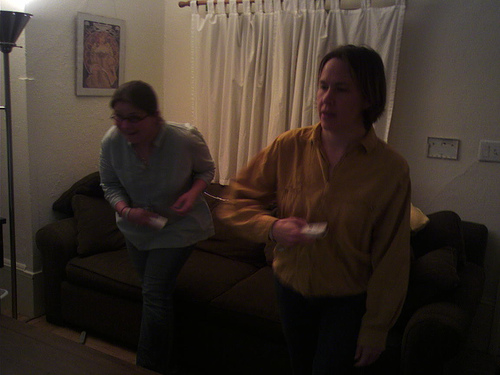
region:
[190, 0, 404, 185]
the white hanging curtain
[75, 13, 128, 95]
the picture is hanging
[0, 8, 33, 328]
the tall floor lamp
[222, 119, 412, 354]
the long sleeved mustard color shirt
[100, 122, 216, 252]
the long sleeved blue shirt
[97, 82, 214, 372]
the glasses on the person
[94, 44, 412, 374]
two people playing video games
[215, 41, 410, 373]
woman holding a Wii controller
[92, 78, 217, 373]
smiling woman wearing glasses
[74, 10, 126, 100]
artwork with white matting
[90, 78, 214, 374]
woman wearing a gray shirt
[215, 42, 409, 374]
woman wearing a tan shirt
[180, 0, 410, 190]
long white curtains hanging off wood rod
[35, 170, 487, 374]
brown cushion couch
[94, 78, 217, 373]
woman wearing blue jeans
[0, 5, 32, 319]
black metal floor lamp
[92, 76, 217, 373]
A person holding a game controller.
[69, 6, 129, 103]
A framed picture on a wall.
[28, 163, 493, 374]
a couch sitting in a living room.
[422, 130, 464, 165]
A small plaque on a wall.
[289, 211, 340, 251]
A gaming controller in a man's hand.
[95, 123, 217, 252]
A person in a t shirt.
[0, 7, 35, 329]
A tall lamp in a room.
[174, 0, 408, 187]
A white curtain over a window.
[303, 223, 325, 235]
a controller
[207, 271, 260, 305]
the couch is brown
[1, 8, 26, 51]
a lamp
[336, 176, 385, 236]
a long sleeve brown shirt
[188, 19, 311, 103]
the curtains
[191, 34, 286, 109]
white curtains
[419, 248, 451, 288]
a pillow on the couch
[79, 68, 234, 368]
The woman to the left is wearing glasses.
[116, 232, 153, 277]
The left foot of the woman.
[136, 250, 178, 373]
The right foot of the woman.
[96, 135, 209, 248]
The long sleeve shirt of the woman.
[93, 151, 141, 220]
The left hand of the woman.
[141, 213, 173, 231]
The white controller in her hand.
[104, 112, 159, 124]
The glasses on the woman's face.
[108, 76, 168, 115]
The hair the woman is wearing.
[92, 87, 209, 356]
Person playing Wii computer game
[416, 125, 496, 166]
Panel and light switch on wall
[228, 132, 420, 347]
Gold colored loose fitting shirt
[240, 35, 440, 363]
Man playing a video game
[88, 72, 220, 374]
woman wearing gray shirt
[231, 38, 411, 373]
man wearing yellow shirt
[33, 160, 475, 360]
brown couch against the wall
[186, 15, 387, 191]
white curtains behind the couch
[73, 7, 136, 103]
picture on the wall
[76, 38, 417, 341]
a couple playing wii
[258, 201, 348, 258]
a remote ina hand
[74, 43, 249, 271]
a lady wearing glasses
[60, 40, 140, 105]
a picture on the wall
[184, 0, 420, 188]
the curtains are white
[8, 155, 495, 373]
the couch is brown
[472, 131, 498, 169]
a white light switch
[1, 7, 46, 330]
a tall floor lamp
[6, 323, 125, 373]
a rug on the floor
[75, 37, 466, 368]
two people standing up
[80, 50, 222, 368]
a person wearing glasses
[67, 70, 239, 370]
a person wearing jeans